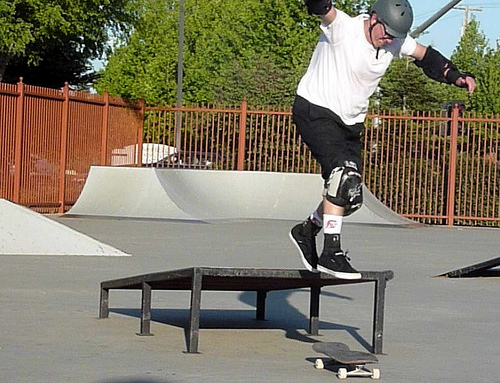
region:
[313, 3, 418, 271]
this is a man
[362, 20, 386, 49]
the man is light skinned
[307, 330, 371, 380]
this is a skateboard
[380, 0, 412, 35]
this is a helmet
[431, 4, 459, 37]
this is the sky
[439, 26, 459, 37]
the sky is blue in color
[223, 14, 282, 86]
this is a tree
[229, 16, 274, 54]
the leaves are green in color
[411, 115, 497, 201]
this is a fence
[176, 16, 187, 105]
this is a pole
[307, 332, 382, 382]
a skateboard in a skate park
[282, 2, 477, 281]
man in a skatepark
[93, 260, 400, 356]
metal ramp at a skate park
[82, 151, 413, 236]
concrete ramp at a skate park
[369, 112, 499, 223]
orange metal fence surrounding a park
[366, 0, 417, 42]
man wearing a safety helmet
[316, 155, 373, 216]
knee pads being worn for safety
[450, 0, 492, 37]
a power pole in the background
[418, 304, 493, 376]
smooth concrete floor of a skate park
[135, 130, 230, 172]
vehicles parked in a parking lot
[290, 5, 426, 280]
man wearing a tshirt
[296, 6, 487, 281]
man wearing black shorts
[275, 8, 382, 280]
man wearing black shoes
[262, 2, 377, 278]
man wearing white socks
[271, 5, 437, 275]
man wearing knee brace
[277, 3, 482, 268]
man wearing arm brace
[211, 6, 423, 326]
man jumping off ramp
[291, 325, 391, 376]
skate board next to ramp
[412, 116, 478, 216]
fence around skate board park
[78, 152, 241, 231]
skate board ramp near fence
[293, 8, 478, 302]
person jumping in the air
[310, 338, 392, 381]
skateboard on the ground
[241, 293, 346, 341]
reflection is on the ground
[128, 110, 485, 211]
fence surrounds the play area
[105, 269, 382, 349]
ramp for jumping on skateboard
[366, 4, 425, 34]
gray helmet on head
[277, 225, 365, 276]
black sneaks on man's feet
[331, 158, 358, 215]
knee pads being worn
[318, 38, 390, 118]
white shirt on man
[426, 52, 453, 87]
elbow pad on left arm